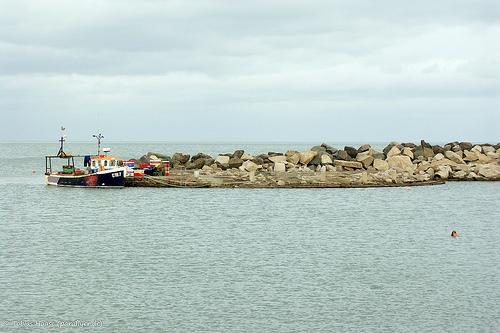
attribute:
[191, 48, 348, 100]
clouds — white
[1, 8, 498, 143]
sky — blue 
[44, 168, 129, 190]
boat — black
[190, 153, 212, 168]
rock — brown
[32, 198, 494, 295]
water — calm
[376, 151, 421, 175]
rock — gray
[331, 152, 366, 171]
rock — gray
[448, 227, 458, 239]
object — orange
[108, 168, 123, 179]
letters — white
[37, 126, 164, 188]
boat — black 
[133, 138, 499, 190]
island — rock